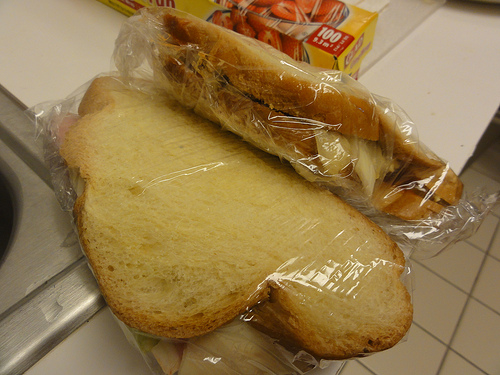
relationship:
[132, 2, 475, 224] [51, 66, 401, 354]
sandwich in plastic bag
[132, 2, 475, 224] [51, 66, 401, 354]
sandwich wrapped plastic bag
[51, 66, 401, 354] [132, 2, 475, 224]
plastic bag wrapped sandwich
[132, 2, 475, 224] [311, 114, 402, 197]
sandwich with meat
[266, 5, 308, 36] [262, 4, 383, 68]
plastic in box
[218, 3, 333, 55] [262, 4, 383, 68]
strawberries picture on box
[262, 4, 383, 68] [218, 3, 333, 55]
box with a strawberries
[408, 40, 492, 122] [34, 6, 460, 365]
counter has on top two wrapped sandwich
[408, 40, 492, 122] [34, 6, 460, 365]
counter with two wrapped sandwich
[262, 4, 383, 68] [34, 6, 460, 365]
box beside two wrapped sandwich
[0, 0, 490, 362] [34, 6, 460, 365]
food prep area with two wrapped sandwich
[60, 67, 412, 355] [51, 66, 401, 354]
potatoe bread in plastic bag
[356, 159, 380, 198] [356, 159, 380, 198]
cheese small cheese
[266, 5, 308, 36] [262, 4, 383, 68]
plastic in a box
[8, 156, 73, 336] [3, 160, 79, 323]
sink of stainless steel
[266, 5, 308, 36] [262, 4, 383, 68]
plastic in length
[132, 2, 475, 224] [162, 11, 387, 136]
bread with crust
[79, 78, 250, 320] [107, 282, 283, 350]
bread with crust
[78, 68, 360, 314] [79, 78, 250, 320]
potatoe bread in form of one slice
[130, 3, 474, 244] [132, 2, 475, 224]
plastic bag with sandwich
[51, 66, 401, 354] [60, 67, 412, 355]
plastic bag with potatoe bread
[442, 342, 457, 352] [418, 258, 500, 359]
grout between tiles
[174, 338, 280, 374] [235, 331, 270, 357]
bag with napkin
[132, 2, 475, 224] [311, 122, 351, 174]
sandwich with meat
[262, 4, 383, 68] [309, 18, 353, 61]
box with label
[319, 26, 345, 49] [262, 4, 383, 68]
100 labeled box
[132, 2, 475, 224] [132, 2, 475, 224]
sandwich with sandwich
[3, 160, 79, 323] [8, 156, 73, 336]
stainless steel material sink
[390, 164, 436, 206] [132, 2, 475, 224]
sauce on sandwich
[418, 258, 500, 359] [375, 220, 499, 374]
tile part of kitchen floor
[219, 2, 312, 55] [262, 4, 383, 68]
wrapped strawberries show on box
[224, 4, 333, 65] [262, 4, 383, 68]
photo on box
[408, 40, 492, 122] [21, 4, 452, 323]
counter with two wrapped sandwich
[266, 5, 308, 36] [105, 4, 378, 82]
plastic in box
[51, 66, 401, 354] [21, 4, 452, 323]
plastic bag sandwiches two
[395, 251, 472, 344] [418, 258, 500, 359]
square floor tile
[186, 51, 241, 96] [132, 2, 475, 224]
lettuce in sandwich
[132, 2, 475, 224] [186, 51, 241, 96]
sandwich with lettuce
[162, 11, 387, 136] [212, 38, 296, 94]
crust color of brown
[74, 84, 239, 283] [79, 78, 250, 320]
yellow tinted bread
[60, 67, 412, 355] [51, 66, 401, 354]
potatoe bread wrapped in plastic bag